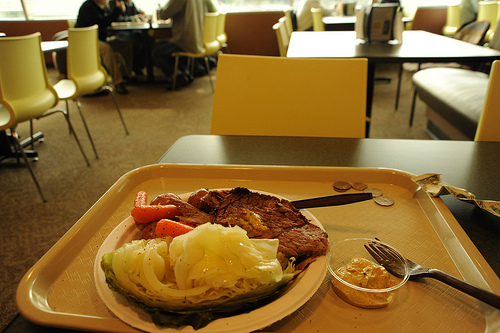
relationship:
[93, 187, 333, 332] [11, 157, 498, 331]
plate on tray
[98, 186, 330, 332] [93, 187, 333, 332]
food on plate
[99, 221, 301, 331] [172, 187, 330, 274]
cabbage with corned beef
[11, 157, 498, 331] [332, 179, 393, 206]
tray under coins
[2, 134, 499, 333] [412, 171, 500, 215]
table under dollar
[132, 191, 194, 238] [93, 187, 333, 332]
carrots on plate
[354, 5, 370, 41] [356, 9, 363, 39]
holder for napkin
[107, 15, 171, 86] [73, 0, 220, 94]
table with people sitting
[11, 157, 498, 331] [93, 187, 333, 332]
tray under plate of food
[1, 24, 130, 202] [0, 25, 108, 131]
chairs made of plastic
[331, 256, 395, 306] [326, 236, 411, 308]
sauce in a plastic cup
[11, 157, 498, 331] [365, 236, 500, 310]
tray under fork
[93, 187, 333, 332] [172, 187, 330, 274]
plate under steak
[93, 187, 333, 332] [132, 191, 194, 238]
plate under carrots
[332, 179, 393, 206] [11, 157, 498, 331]
coins sitting on tray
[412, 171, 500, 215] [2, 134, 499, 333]
dollar on table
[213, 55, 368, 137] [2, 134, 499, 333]
chair next to table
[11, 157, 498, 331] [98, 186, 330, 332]
tray under food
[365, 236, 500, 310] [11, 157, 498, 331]
fork on tray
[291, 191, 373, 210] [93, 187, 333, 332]
fork on plate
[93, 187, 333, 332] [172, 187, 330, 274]
plate under meat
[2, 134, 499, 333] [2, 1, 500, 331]
table in restaurant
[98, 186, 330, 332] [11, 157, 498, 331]
food on tray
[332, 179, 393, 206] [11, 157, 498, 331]
coins on tray